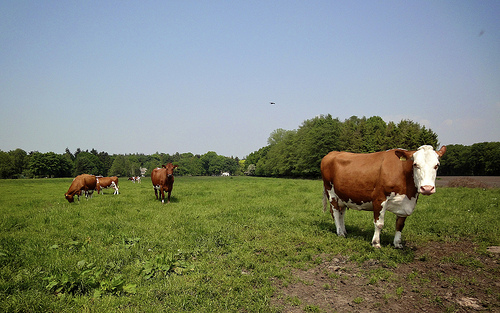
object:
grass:
[0, 174, 500, 312]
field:
[0, 176, 500, 312]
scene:
[0, 0, 499, 313]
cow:
[97, 174, 118, 195]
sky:
[0, 1, 500, 160]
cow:
[64, 173, 98, 203]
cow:
[150, 162, 181, 203]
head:
[394, 144, 448, 196]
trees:
[0, 147, 242, 179]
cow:
[320, 143, 445, 249]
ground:
[0, 173, 500, 313]